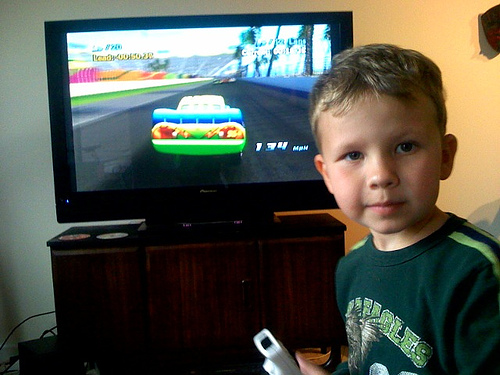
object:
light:
[479, 2, 499, 55]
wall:
[0, 0, 499, 375]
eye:
[393, 140, 423, 158]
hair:
[306, 42, 450, 158]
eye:
[334, 148, 369, 165]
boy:
[294, 42, 499, 374]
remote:
[251, 328, 298, 373]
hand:
[294, 347, 332, 373]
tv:
[41, 11, 354, 247]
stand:
[44, 211, 348, 368]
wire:
[0, 309, 56, 351]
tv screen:
[65, 23, 343, 194]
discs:
[92, 231, 132, 240]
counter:
[45, 211, 347, 375]